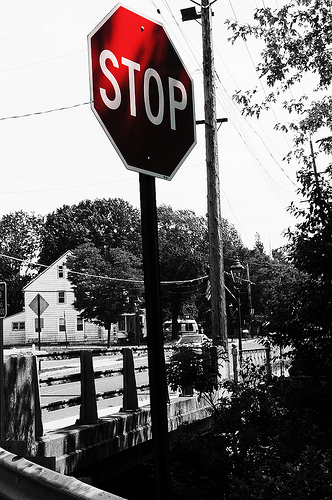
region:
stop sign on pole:
[80, 3, 208, 190]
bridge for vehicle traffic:
[50, 371, 224, 439]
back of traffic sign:
[27, 290, 52, 319]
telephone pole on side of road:
[200, 109, 221, 257]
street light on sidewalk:
[229, 248, 246, 356]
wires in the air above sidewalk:
[68, 262, 237, 317]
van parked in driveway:
[160, 313, 205, 337]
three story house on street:
[16, 247, 132, 348]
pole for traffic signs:
[34, 328, 44, 372]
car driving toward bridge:
[165, 330, 220, 357]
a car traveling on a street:
[173, 334, 215, 355]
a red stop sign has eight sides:
[81, 0, 214, 186]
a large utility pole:
[191, 1, 232, 388]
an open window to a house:
[55, 289, 67, 305]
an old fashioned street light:
[226, 251, 249, 374]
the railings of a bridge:
[0, 342, 243, 446]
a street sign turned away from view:
[24, 291, 54, 364]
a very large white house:
[2, 250, 150, 351]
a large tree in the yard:
[67, 243, 149, 352]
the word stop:
[96, 47, 190, 133]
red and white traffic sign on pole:
[66, 0, 206, 460]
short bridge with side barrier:
[7, 332, 243, 459]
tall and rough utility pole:
[177, 0, 226, 347]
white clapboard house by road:
[2, 249, 123, 340]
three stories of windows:
[51, 259, 67, 332]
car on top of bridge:
[131, 307, 224, 428]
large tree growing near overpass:
[223, 173, 319, 494]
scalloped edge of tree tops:
[4, 195, 250, 244]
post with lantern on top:
[223, 246, 243, 378]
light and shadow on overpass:
[7, 333, 180, 461]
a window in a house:
[55, 289, 68, 303]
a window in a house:
[56, 267, 68, 280]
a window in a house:
[58, 316, 69, 334]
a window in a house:
[75, 313, 86, 331]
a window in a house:
[34, 318, 43, 327]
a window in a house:
[13, 319, 29, 328]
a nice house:
[0, 246, 117, 350]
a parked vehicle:
[173, 328, 208, 360]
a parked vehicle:
[161, 317, 198, 339]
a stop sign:
[81, 0, 194, 452]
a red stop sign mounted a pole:
[87, 2, 197, 181]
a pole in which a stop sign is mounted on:
[138, 172, 170, 498]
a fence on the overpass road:
[34, 341, 224, 434]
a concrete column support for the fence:
[1, 350, 42, 443]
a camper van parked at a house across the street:
[163, 320, 198, 340]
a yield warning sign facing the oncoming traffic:
[28, 293, 48, 350]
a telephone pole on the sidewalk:
[180, 0, 226, 378]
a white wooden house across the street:
[21, 249, 145, 344]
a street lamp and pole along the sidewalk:
[228, 250, 243, 378]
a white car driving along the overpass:
[171, 334, 211, 359]